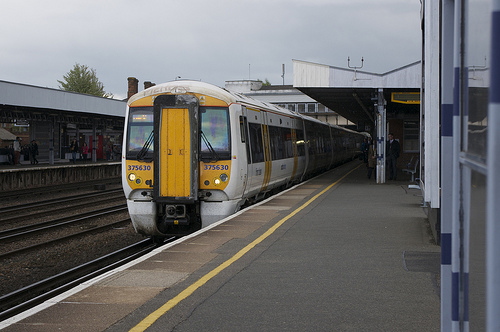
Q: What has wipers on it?
A: Train windows.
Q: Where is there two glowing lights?
A: Front of train.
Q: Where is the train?
A: Station.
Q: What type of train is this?
A: Passenger.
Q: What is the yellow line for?
A: Passenger warning.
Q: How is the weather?
A: Cloudy.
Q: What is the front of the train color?
A: Yellow and white.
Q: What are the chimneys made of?
A: Brick.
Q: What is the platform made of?
A: Cement.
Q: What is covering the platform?
A: Roof.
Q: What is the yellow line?
A: It marks the platform edge.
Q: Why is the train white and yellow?
A: To identify the train line.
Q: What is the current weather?
A: Cloudy.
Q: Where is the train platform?
A: It is outdoors.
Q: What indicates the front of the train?
A: Its yellow paint.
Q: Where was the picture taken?
A: A train station.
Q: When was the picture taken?
A: Daytime.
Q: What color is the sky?
A: Gray.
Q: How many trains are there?
A: One.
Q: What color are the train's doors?
A: Yellow.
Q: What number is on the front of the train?
A: 375630.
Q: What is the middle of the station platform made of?
A: Asphalt.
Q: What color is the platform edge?
A: White.